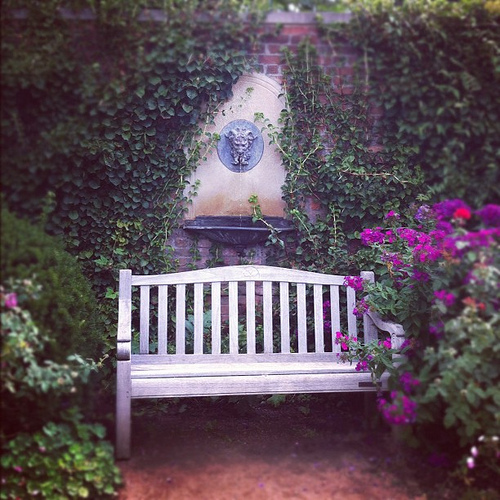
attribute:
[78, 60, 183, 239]
plants — green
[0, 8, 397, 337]
wall — brick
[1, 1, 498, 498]
plants — green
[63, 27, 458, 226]
wall — retaining